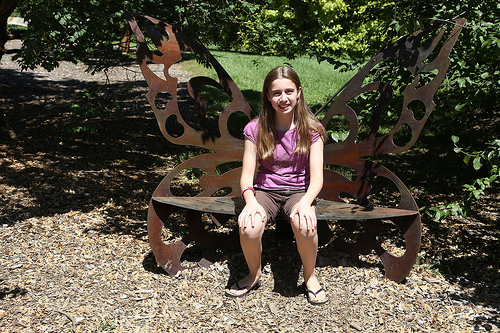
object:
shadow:
[0, 70, 500, 333]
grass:
[195, 51, 354, 106]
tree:
[0, 0, 500, 120]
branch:
[31, 2, 91, 33]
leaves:
[12, 92, 467, 328]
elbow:
[237, 168, 247, 178]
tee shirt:
[243, 122, 324, 194]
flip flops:
[300, 281, 330, 305]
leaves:
[16, 8, 480, 82]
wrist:
[239, 186, 257, 202]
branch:
[432, 169, 483, 230]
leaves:
[430, 176, 484, 219]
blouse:
[243, 120, 324, 191]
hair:
[256, 66, 310, 175]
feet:
[223, 270, 261, 297]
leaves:
[217, 7, 377, 62]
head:
[264, 66, 303, 115]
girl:
[222, 63, 331, 307]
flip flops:
[224, 277, 259, 298]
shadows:
[2, 66, 490, 331]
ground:
[2, 19, 498, 330]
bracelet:
[240, 186, 257, 200]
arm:
[240, 120, 266, 230]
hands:
[236, 200, 265, 230]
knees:
[237, 216, 263, 242]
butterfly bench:
[122, 7, 468, 282]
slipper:
[221, 277, 259, 299]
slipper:
[301, 281, 329, 304]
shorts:
[250, 188, 315, 222]